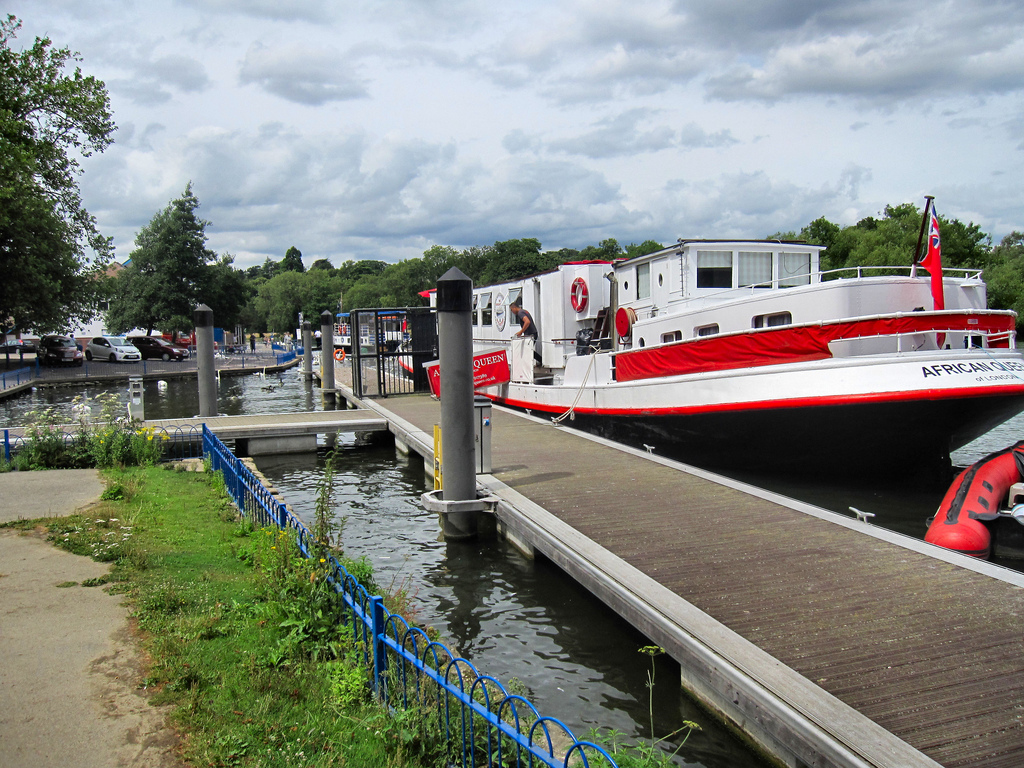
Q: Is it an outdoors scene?
A: Yes, it is outdoors.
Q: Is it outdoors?
A: Yes, it is outdoors.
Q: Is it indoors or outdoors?
A: It is outdoors.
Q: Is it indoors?
A: No, it is outdoors.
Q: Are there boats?
A: Yes, there is a boat.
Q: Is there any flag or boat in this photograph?
A: Yes, there is a boat.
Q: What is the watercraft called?
A: The watercraft is a boat.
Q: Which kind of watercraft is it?
A: The watercraft is a boat.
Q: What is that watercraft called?
A: This is a boat.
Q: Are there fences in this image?
A: Yes, there is a fence.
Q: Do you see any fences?
A: Yes, there is a fence.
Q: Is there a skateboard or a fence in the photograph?
A: Yes, there is a fence.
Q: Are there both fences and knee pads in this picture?
A: No, there is a fence but no knee pads.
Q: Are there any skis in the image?
A: No, there are no skis.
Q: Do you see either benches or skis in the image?
A: No, there are no skis or benches.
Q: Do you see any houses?
A: No, there are no houses.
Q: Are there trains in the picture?
A: No, there are no trains.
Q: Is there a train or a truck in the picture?
A: No, there are no trains or trucks.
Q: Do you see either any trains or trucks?
A: No, there are no trains or trucks.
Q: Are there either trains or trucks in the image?
A: No, there are no trains or trucks.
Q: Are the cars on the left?
A: Yes, the cars are on the left of the image.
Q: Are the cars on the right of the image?
A: No, the cars are on the left of the image.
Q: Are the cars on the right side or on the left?
A: The cars are on the left of the image.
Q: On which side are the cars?
A: The cars are on the left of the image.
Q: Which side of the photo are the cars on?
A: The cars are on the left of the image.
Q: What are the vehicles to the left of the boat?
A: The vehicles are cars.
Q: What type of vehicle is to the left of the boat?
A: The vehicles are cars.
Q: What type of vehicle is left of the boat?
A: The vehicles are cars.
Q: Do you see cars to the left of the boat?
A: Yes, there are cars to the left of the boat.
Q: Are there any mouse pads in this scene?
A: No, there are no mouse pads.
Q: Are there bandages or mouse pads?
A: No, there are no mouse pads or bandages.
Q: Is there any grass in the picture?
A: Yes, there is grass.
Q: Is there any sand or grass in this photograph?
A: Yes, there is grass.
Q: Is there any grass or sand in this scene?
A: Yes, there is grass.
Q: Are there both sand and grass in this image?
A: No, there is grass but no sand.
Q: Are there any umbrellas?
A: No, there are no umbrellas.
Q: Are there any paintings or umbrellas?
A: No, there are no umbrellas or paintings.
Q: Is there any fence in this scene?
A: Yes, there is a fence.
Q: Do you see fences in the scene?
A: Yes, there is a fence.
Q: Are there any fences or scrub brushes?
A: Yes, there is a fence.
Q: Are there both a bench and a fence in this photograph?
A: No, there is a fence but no benches.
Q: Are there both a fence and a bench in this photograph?
A: No, there is a fence but no benches.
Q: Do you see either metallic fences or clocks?
A: Yes, there is a metal fence.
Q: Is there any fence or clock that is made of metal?
A: Yes, the fence is made of metal.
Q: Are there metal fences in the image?
A: Yes, there is a metal fence.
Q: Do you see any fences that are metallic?
A: Yes, there is a fence that is metallic.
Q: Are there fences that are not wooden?
A: Yes, there is a metallic fence.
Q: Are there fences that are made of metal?
A: Yes, there is a fence that is made of metal.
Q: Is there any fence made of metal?
A: Yes, there is a fence that is made of metal.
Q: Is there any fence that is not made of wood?
A: Yes, there is a fence that is made of metal.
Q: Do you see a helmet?
A: No, there are no helmets.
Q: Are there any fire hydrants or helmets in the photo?
A: No, there are no helmets or fire hydrants.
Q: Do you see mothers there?
A: No, there are no mothers.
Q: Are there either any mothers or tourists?
A: No, there are no mothers or tourists.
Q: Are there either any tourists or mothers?
A: No, there are no mothers or tourists.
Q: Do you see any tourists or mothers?
A: No, there are no mothers or tourists.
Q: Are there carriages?
A: No, there are no carriages.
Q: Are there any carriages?
A: No, there are no carriages.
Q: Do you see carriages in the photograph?
A: No, there are no carriages.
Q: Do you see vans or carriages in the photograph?
A: No, there are no carriages or vans.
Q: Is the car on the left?
A: Yes, the car is on the left of the image.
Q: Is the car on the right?
A: No, the car is on the left of the image.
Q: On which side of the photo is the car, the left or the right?
A: The car is on the left of the image.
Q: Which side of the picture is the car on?
A: The car is on the left of the image.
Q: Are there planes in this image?
A: No, there are no planes.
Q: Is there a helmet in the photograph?
A: No, there are no helmets.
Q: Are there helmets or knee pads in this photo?
A: No, there are no helmets or knee pads.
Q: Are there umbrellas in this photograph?
A: No, there are no umbrellas.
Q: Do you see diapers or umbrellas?
A: No, there are no umbrellas or diapers.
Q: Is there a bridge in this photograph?
A: No, there are no bridges.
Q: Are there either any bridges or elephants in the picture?
A: No, there are no bridges or elephants.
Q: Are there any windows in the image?
A: Yes, there is a window.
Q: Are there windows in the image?
A: Yes, there is a window.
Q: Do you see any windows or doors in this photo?
A: Yes, there is a window.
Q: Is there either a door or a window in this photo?
A: Yes, there is a window.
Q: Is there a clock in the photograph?
A: No, there are no clocks.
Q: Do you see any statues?
A: No, there are no statues.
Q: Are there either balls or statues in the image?
A: No, there are no statues or balls.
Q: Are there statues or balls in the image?
A: No, there are no statues or balls.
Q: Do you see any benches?
A: No, there are no benches.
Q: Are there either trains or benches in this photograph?
A: No, there are no benches or trains.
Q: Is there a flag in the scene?
A: Yes, there is a flag.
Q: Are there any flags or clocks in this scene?
A: Yes, there is a flag.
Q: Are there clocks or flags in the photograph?
A: Yes, there is a flag.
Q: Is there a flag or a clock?
A: Yes, there is a flag.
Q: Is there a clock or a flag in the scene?
A: Yes, there is a flag.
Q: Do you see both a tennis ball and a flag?
A: No, there is a flag but no tennis balls.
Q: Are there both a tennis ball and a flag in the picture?
A: No, there is a flag but no tennis balls.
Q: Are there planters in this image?
A: No, there are no planters.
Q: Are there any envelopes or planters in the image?
A: No, there are no planters or envelopes.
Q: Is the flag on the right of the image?
A: Yes, the flag is on the right of the image.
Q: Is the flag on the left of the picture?
A: No, the flag is on the right of the image.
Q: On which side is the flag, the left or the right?
A: The flag is on the right of the image.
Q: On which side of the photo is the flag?
A: The flag is on the right of the image.